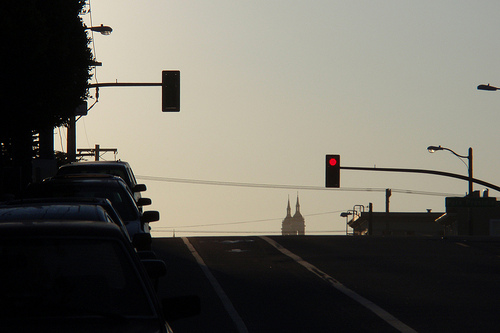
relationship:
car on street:
[0, 220, 173, 332] [124, 235, 498, 331]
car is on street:
[2, 198, 152, 326] [25, 228, 472, 326]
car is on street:
[52, 172, 131, 208] [25, 228, 472, 326]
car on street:
[0, 220, 173, 332] [153, 222, 387, 322]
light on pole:
[316, 127, 345, 207] [341, 158, 499, 181]